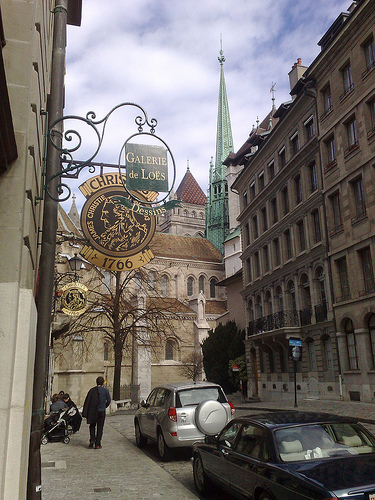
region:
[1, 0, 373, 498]
picture is of geneva, switzerland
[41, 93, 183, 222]
elaborate brace for swinging wall sign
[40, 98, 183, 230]
brace/bracket is kind of art nouveau-ish, ending in a swinging cirlce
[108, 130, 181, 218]
inside the swinging circle sign, the words 'galerie de loes'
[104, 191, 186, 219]
beneath the circle is a swinging banner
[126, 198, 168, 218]
on the banner, the word 'dessins'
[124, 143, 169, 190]
'galerie de loes' is inside a square inside the circle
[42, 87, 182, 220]
all parts of the sign are dark green, all letters are goldtone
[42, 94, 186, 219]
sign is either all metal, or the brace/bracket/connectors are metal & the signs themselves are wood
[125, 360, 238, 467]
This is a car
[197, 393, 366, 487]
This is a car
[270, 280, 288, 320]
This is a window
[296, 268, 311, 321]
This is a window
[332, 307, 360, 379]
This is a window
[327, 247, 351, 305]
This is a window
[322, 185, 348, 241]
This is a window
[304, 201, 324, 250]
This is a window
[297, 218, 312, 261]
This is a window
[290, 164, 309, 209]
This is a window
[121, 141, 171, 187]
The sign is black.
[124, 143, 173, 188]
The sign has gold lettering.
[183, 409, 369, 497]
The black car is parked.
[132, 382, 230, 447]
The car is parked.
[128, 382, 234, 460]
The car is next to the sidewalk.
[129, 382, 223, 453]
The car is silver.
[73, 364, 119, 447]
The man is wearing a grey shirt.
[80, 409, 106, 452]
The man is wearing black pants.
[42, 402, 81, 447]
The stroller is black.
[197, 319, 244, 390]
The bushes are green and leafy.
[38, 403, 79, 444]
baby carriege on the sidewalk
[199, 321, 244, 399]
green bush in the corner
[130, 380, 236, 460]
car parked on the street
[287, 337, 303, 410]
signal on the sidewalk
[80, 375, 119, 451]
man walking on the sidewalk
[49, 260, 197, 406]
tree without leaves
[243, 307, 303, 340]
black fence on the balcony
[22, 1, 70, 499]
metal pole next to the wall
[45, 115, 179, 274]
store signs hanging from post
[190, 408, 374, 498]
car parked on the street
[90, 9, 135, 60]
white clouds in blue sky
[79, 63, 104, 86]
white clouds in blue sky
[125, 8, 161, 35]
white clouds in blue sky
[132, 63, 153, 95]
white clouds in blue sky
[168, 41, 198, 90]
white clouds in blue sky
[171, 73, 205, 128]
v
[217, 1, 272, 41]
white clouds in blue sky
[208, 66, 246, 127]
green steeple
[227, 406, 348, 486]
black car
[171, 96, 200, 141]
white clouds in blue sky